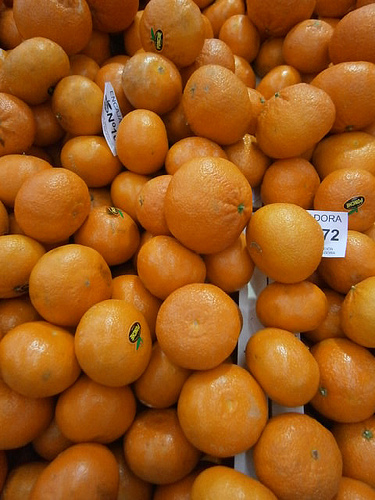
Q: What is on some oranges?
A: Labels.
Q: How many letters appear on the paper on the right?
A: 4.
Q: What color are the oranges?
A: Orange.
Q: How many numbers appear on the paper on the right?
A: 2.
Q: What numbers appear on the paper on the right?
A: 7,2.